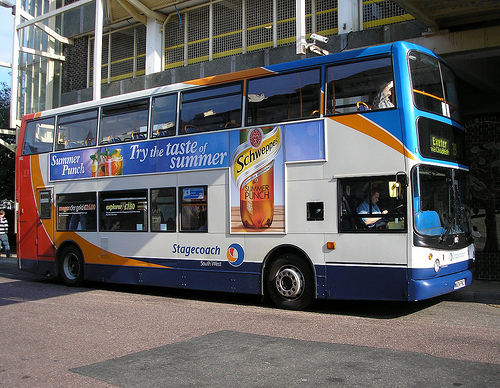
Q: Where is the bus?
A: On the side of the street.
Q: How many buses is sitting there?
A: One.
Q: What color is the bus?
A: Blue, white and red.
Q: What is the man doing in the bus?
A: Waiting.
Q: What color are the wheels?
A: Black.